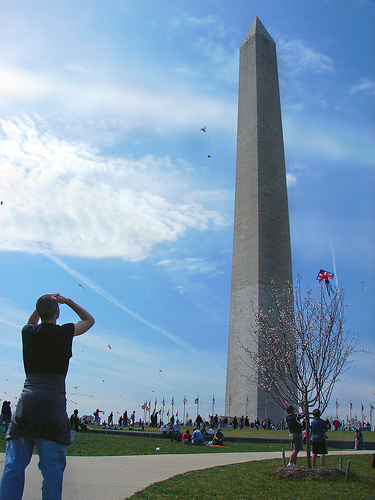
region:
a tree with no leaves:
[237, 276, 369, 460]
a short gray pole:
[342, 456, 354, 479]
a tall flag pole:
[192, 393, 202, 417]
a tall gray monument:
[223, 14, 304, 423]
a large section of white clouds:
[0, 116, 231, 268]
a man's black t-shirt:
[21, 321, 77, 371]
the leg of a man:
[34, 439, 67, 498]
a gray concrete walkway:
[1, 449, 373, 498]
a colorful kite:
[315, 268, 337, 297]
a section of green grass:
[126, 451, 374, 498]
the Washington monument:
[211, 7, 312, 424]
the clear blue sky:
[310, 12, 352, 40]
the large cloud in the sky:
[15, 133, 144, 231]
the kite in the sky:
[286, 260, 346, 288]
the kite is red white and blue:
[302, 258, 342, 298]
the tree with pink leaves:
[244, 258, 346, 479]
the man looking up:
[16, 282, 108, 497]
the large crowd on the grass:
[70, 410, 372, 453]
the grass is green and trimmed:
[82, 437, 146, 447]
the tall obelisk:
[229, 11, 319, 426]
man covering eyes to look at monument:
[15, 286, 84, 499]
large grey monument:
[232, 18, 294, 422]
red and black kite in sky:
[314, 268, 336, 291]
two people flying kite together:
[284, 403, 330, 473]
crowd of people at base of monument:
[67, 407, 367, 443]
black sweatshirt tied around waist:
[13, 378, 76, 441]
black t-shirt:
[21, 320, 72, 381]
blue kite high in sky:
[201, 125, 206, 133]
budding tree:
[251, 271, 339, 421]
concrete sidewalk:
[4, 449, 372, 496]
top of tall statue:
[232, 8, 280, 34]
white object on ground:
[149, 443, 173, 459]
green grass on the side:
[86, 441, 134, 452]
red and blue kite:
[301, 262, 345, 309]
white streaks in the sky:
[61, 261, 194, 352]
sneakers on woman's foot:
[278, 456, 308, 468]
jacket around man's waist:
[6, 367, 81, 452]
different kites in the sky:
[94, 348, 165, 393]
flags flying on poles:
[142, 376, 225, 407]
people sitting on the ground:
[159, 417, 233, 449]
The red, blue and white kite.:
[312, 266, 338, 298]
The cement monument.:
[228, 6, 299, 430]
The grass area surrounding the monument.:
[48, 408, 374, 450]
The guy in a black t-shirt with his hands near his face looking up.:
[16, 315, 85, 373]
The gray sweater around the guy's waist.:
[6, 355, 77, 450]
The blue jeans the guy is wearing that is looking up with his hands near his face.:
[1, 429, 72, 499]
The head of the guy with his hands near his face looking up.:
[31, 292, 62, 322]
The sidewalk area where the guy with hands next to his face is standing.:
[16, 445, 188, 496]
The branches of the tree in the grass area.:
[228, 268, 350, 470]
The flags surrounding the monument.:
[115, 379, 373, 428]